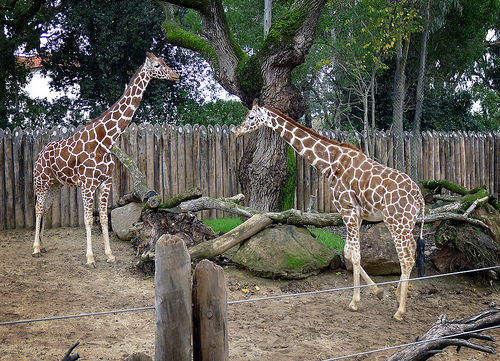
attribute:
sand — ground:
[1, 252, 498, 359]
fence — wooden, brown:
[0, 115, 499, 235]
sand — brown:
[1, 224, 498, 359]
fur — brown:
[342, 159, 379, 199]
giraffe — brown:
[234, 101, 449, 328]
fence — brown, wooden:
[5, 122, 498, 252]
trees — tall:
[302, 0, 433, 184]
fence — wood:
[0, 125, 497, 224]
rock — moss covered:
[225, 213, 337, 275]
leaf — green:
[392, 35, 397, 42]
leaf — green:
[389, 40, 394, 46]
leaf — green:
[384, 43, 390, 48]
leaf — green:
[360, 26, 365, 33]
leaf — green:
[389, 21, 395, 26]